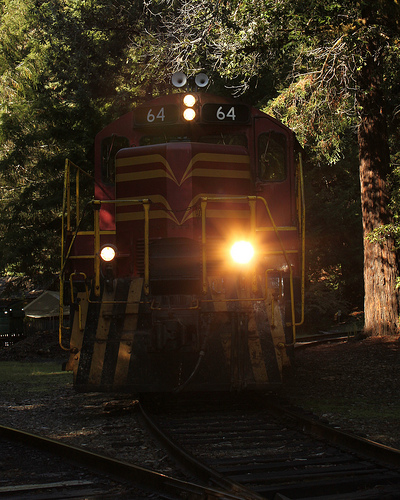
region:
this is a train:
[54, 85, 337, 407]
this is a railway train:
[221, 436, 395, 494]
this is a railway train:
[168, 409, 341, 479]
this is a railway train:
[32, 430, 108, 498]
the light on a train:
[211, 207, 273, 289]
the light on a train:
[97, 232, 131, 288]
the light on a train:
[177, 88, 198, 136]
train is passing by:
[52, 86, 319, 399]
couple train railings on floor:
[118, 378, 399, 498]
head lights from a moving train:
[203, 216, 281, 277]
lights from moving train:
[91, 233, 123, 264]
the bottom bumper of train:
[63, 267, 296, 405]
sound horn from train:
[162, 69, 218, 91]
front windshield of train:
[253, 120, 293, 182]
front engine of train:
[101, 137, 259, 298]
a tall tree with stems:
[121, 0, 392, 350]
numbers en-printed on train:
[142, 101, 244, 123]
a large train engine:
[25, 70, 306, 399]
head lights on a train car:
[91, 236, 269, 269]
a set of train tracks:
[205, 415, 356, 486]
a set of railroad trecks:
[178, 413, 358, 492]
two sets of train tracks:
[37, 418, 369, 498]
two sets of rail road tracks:
[13, 419, 371, 491]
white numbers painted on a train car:
[211, 100, 239, 124]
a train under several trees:
[19, 8, 369, 202]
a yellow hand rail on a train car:
[84, 189, 308, 266]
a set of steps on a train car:
[55, 163, 115, 280]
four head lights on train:
[66, 86, 312, 299]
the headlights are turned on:
[84, 82, 326, 300]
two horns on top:
[163, 62, 222, 97]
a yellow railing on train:
[60, 183, 283, 328]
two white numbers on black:
[127, 92, 259, 133]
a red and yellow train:
[60, 82, 305, 297]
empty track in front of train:
[26, 392, 383, 494]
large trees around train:
[7, 3, 396, 383]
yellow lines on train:
[112, 147, 290, 255]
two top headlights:
[175, 88, 202, 126]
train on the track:
[45, 71, 314, 393]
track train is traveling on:
[119, 404, 387, 490]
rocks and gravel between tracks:
[35, 415, 137, 450]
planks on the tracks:
[230, 450, 357, 475]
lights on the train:
[88, 229, 258, 266]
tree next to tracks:
[264, 8, 393, 378]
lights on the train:
[178, 99, 196, 130]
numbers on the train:
[137, 103, 248, 124]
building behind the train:
[10, 286, 72, 333]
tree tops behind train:
[4, 7, 395, 137]